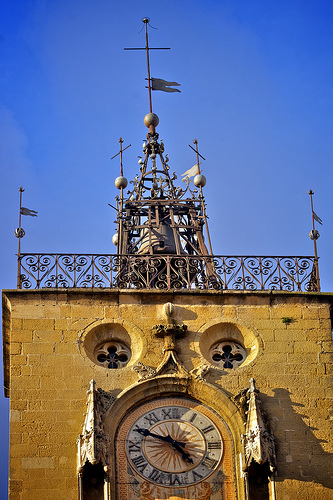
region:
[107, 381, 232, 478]
Clock on an old building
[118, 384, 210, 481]
A clock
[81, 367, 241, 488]
Roman numerals on the clock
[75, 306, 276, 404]
Fancy ornate stone work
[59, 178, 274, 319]
Cast iron work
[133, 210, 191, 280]
A Bell on top of the tower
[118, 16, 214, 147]
Top of the tower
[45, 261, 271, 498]
Stone tower with a clock on it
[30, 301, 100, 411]
Stone and masonry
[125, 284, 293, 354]
Very old tower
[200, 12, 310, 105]
this is the sky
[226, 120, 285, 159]
the sky is blue in color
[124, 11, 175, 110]
this is a cross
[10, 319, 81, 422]
this is a wall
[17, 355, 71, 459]
the wall is brown in color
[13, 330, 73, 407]
the wall is made of stones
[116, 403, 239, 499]
this is the door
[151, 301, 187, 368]
this is a statue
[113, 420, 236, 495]
the door is closed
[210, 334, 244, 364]
this is an opening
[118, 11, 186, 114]
Large cross on top of the building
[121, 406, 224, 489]
The clock on the side of the building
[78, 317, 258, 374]
The two circular windows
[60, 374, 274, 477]
The triangular shapes near the clock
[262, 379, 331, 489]
The shadow of the rectangular object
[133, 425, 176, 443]
The minutes hand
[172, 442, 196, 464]
The hour hand on the clock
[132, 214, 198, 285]
The bell on top of the tower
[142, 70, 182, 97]
The flag on the large cross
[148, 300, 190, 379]
The decoration between the two circular windows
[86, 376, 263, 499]
Building has a white clock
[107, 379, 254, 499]
Clock is at 5:50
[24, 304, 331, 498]
Building is tan colored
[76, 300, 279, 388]
Building has cross designs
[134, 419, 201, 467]
Clock handles are black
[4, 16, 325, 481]
Photo was taken in the daytime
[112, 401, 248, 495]
Clock numbers are in roman numerals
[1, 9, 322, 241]
The sky is clear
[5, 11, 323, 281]
The sky is bright blue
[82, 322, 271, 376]
Cross designs are circular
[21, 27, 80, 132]
the sky is blue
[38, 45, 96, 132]
the sky is clear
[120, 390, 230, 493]
the clock is circle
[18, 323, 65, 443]
the wall is yellow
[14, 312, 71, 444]
the wall is made of brick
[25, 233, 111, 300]
the railing is black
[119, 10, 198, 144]
the cross is metal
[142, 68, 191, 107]
the flag is facing right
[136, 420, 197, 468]
the dials are black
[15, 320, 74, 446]
the brick is worn